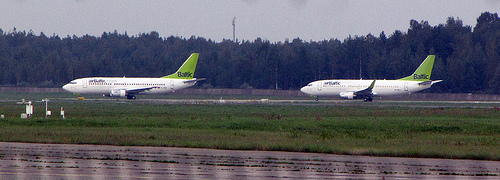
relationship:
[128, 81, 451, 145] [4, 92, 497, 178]
grass along runway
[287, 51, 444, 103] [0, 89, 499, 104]
airplane sitting on runway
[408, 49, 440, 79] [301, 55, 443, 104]
tail of an airplane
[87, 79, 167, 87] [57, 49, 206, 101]
windows of an airplane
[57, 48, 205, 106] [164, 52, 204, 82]
plane has a tail